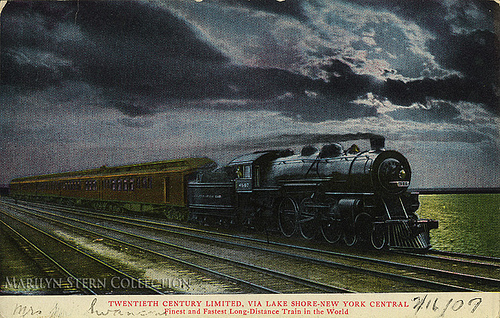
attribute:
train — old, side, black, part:
[8, 131, 442, 256]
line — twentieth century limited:
[62, 265, 453, 297]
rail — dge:
[126, 191, 409, 302]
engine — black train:
[187, 130, 446, 262]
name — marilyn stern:
[5, 264, 189, 301]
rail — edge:
[0, 190, 500, 292]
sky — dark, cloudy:
[77, 26, 454, 159]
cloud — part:
[224, 27, 497, 130]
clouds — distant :
[0, 0, 500, 146]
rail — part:
[117, 226, 162, 253]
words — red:
[105, 299, 409, 316]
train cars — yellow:
[46, 136, 433, 246]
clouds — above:
[4, 3, 497, 187]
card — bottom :
[114, 296, 420, 316]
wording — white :
[6, 266, 196, 292]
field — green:
[448, 195, 484, 235]